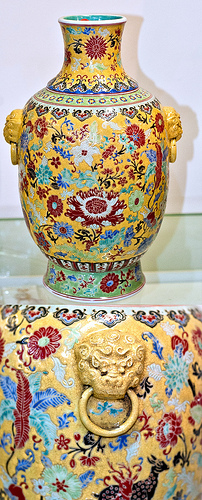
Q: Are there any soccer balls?
A: No, there are no soccer balls.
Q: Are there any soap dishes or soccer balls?
A: No, there are no soccer balls or soap dishes.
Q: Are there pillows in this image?
A: No, there are no pillows.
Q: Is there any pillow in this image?
A: No, there are no pillows.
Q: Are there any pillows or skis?
A: No, there are no pillows or skis.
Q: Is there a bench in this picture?
A: No, there are no benches.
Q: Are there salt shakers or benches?
A: No, there are no benches or salt shakers.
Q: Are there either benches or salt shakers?
A: No, there are no benches or salt shakers.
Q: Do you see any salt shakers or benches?
A: No, there are no benches or salt shakers.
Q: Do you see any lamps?
A: No, there are no lamps.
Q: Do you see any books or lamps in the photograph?
A: No, there are no lamps or books.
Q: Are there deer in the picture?
A: Yes, there is a deer.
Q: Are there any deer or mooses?
A: Yes, there is a deer.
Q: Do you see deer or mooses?
A: Yes, there is a deer.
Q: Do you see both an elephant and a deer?
A: No, there is a deer but no elephants.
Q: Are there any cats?
A: No, there are no cats.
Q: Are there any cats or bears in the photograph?
A: No, there are no cats or bears.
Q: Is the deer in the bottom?
A: Yes, the deer is in the bottom of the image.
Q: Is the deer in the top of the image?
A: No, the deer is in the bottom of the image.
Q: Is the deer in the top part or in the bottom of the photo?
A: The deer is in the bottom of the image.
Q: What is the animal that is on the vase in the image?
A: The animal is a deer.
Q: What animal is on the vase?
A: The animal is a deer.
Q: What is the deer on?
A: The deer is on the vase.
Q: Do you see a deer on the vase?
A: Yes, there is a deer on the vase.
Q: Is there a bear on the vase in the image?
A: No, there is a deer on the vase.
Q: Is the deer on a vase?
A: Yes, the deer is on a vase.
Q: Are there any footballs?
A: No, there are no footballs.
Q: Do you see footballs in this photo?
A: No, there are no footballs.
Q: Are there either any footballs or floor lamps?
A: No, there are no footballs or floor lamps.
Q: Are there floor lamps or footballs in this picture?
A: No, there are no footballs or floor lamps.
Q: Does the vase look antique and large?
A: Yes, the vase is antique and large.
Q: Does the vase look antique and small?
A: No, the vase is antique but large.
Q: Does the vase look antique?
A: Yes, the vase is antique.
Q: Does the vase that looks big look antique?
A: Yes, the vase is antique.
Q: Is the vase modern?
A: No, the vase is antique.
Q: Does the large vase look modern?
A: No, the vase is antique.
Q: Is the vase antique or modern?
A: The vase is antique.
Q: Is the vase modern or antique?
A: The vase is antique.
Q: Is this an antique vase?
A: Yes, this is an antique vase.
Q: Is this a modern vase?
A: No, this is an antique vase.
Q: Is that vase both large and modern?
A: No, the vase is large but antique.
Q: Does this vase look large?
A: Yes, the vase is large.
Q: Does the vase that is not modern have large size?
A: Yes, the vase is large.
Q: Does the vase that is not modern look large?
A: Yes, the vase is large.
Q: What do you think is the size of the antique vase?
A: The vase is large.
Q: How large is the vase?
A: The vase is large.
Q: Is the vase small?
A: No, the vase is large.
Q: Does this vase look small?
A: No, the vase is large.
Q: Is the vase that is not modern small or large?
A: The vase is large.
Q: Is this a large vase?
A: Yes, this is a large vase.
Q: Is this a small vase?
A: No, this is a large vase.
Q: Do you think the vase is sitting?
A: Yes, the vase is sitting.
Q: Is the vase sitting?
A: Yes, the vase is sitting.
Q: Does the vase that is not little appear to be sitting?
A: Yes, the vase is sitting.